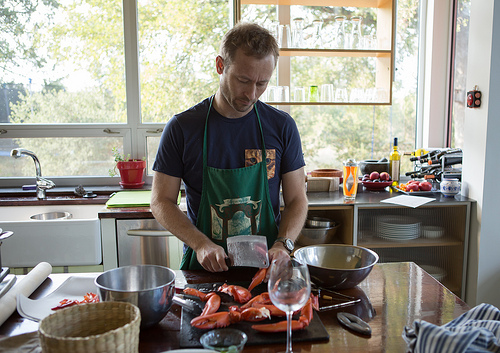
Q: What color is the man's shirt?
A: Black.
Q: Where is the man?
A: A kitchen.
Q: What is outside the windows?
A: Trees.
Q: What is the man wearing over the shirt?
A: An apron.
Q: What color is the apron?
A: Green.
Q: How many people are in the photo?
A: One.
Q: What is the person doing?
A: Cooking.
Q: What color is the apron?
A: Green.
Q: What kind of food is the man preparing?
A: Lobster.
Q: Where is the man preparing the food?
A: Kitchen.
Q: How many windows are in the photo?
A: One.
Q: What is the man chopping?
A: Lobsters.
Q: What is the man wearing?
A: An apron.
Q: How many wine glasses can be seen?
A: One.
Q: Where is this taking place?
A: In a kitchen.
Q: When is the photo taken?
A: During the day.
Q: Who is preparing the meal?
A: A man.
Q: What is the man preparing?
A: Lobster.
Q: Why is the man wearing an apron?
A: To protect his clothing from a mess.